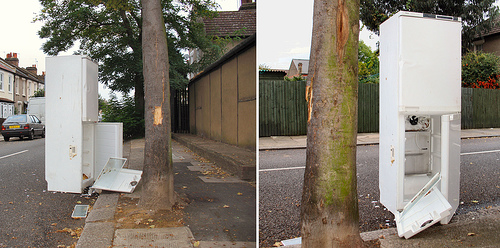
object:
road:
[0, 124, 98, 246]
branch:
[40, 0, 199, 62]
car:
[2, 114, 44, 142]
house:
[282, 58, 312, 85]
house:
[461, 9, 498, 85]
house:
[0, 59, 46, 124]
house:
[182, 0, 257, 79]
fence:
[258, 78, 498, 138]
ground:
[397, 124, 449, 156]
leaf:
[175, 14, 205, 39]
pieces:
[64, 150, 143, 194]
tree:
[297, 0, 376, 247]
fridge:
[377, 10, 463, 237]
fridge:
[43, 54, 144, 194]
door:
[193, 71, 212, 139]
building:
[1, 47, 46, 116]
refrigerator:
[40, 53, 143, 192]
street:
[0, 136, 97, 235]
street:
[260, 135, 499, 247]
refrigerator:
[379, 10, 462, 233]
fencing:
[258, 78, 306, 137]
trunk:
[138, 0, 173, 218]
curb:
[359, 210, 497, 247]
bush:
[458, 43, 498, 88]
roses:
[473, 75, 497, 88]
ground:
[0, 137, 255, 245]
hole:
[335, 1, 351, 48]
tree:
[33, 0, 250, 217]